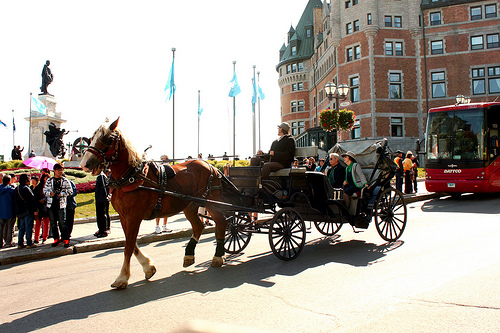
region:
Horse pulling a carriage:
[78, 115, 409, 290]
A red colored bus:
[420, 92, 499, 199]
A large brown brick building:
[274, 1, 498, 141]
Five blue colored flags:
[160, 43, 267, 159]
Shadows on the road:
[1, 232, 405, 331]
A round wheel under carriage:
[266, 204, 306, 263]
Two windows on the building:
[463, 61, 498, 95]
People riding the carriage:
[248, 121, 373, 197]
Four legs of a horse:
[107, 207, 231, 289]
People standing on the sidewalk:
[1, 164, 79, 265]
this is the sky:
[93, 32, 133, 102]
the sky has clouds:
[74, 13, 129, 80]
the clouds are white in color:
[87, 14, 127, 82]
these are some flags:
[153, 42, 263, 148]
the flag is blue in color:
[231, 79, 241, 87]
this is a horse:
[75, 114, 235, 299]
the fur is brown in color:
[115, 188, 137, 211]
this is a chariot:
[227, 134, 398, 255]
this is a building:
[261, 16, 419, 113]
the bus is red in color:
[453, 177, 473, 189]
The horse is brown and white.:
[81, 116, 243, 293]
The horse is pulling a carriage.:
[81, 115, 410, 290]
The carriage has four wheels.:
[218, 186, 407, 260]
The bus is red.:
[421, 97, 498, 196]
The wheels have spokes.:
[217, 188, 407, 260]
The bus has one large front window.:
[425, 105, 499, 170]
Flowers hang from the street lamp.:
[317, 106, 357, 130]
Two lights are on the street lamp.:
[321, 78, 351, 98]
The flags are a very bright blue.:
[166, 56, 268, 118]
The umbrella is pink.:
[21, 153, 58, 172]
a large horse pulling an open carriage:
[78, 113, 406, 288]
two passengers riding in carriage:
[321, 147, 374, 202]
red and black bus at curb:
[421, 98, 497, 204]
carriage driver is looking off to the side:
[259, 121, 299, 161]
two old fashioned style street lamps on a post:
[320, 78, 357, 145]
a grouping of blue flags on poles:
[164, 46, 265, 161]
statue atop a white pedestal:
[29, 59, 62, 156]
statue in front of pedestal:
[26, 116, 70, 162]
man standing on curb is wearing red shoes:
[41, 161, 79, 249]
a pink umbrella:
[23, 156, 58, 171]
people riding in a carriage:
[52, 119, 417, 294]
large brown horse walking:
[45, 116, 237, 293]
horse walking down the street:
[75, 134, 234, 287]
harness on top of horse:
[64, 98, 239, 288]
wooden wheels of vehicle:
[275, 186, 422, 256]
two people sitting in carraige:
[310, 143, 367, 205]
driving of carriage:
[242, 110, 299, 182]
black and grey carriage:
[247, 143, 414, 262]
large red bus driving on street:
[427, 98, 498, 200]